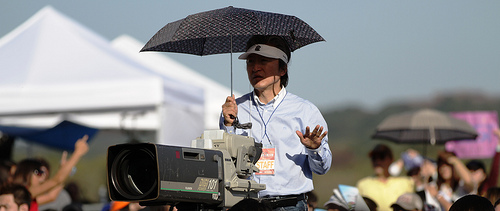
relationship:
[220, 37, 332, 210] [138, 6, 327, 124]
person holding an umbrella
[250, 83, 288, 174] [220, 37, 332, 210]
tag hanging on person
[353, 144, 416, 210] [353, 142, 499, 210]
person in crowd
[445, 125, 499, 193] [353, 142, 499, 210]
person in crowd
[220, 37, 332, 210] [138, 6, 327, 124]
person holding umbrella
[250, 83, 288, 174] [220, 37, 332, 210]
tag around person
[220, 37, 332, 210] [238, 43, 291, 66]
person wearing a visor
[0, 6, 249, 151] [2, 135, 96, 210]
tent over people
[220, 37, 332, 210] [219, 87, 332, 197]
person wearing a shirt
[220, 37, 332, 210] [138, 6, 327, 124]
person carrying umbrella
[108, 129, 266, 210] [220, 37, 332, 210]
camera in front of person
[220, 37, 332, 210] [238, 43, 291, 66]
person wearing visor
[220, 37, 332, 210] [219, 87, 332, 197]
person wearing shirt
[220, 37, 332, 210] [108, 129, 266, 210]
person behind a camera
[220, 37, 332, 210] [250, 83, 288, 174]
person wearing a tag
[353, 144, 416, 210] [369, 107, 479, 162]
person under umbrella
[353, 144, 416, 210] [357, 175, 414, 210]
person wearing shirt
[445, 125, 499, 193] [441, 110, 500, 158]
person holding square